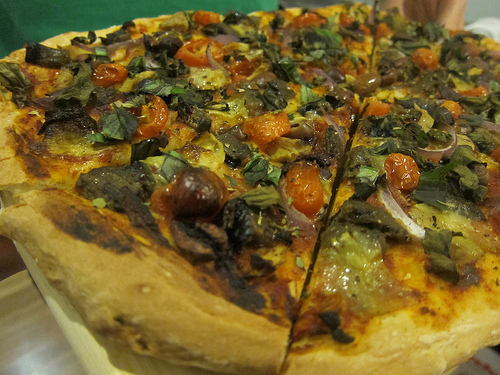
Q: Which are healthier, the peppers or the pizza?
A: The peppers are healthier than the pizza.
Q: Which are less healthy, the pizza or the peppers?
A: The pizza are less healthy than the peppers.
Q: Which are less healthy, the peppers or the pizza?
A: The pizza are less healthy than the peppers.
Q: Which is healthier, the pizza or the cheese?
A: The cheese is healthier than the pizza.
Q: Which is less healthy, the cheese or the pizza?
A: The pizza is less healthy than the cheese.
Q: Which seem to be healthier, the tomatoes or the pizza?
A: The tomatoes are healthier than the pizza.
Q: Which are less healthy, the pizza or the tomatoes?
A: The pizza are less healthy than the tomatoes.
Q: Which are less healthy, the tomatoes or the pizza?
A: The pizza are less healthy than the tomatoes.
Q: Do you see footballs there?
A: No, there are no footballs.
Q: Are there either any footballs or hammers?
A: No, there are no footballs or hammers.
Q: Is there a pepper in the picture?
A: Yes, there are peppers.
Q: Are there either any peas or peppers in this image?
A: Yes, there are peppers.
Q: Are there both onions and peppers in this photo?
A: Yes, there are both peppers and an onion.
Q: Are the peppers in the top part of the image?
A: Yes, the peppers are in the top of the image.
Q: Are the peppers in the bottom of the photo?
A: No, the peppers are in the top of the image.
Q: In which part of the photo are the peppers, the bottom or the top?
A: The peppers are in the top of the image.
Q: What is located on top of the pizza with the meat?
A: The peppers are on top of the pizza.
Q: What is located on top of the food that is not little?
A: The peppers are on top of the pizza.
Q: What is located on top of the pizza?
A: The peppers are on top of the pizza.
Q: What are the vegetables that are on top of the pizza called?
A: The vegetables are peppers.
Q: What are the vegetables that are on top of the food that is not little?
A: The vegetables are peppers.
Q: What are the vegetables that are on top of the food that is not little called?
A: The vegetables are peppers.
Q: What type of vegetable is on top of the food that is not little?
A: The vegetables are peppers.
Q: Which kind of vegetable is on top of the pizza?
A: The vegetables are peppers.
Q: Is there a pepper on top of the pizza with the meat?
A: Yes, there are peppers on top of the pizza.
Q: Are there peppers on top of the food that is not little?
A: Yes, there are peppers on top of the pizza.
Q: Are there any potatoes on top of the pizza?
A: No, there are peppers on top of the pizza.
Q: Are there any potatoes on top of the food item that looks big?
A: No, there are peppers on top of the pizza.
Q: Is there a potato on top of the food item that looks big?
A: No, there are peppers on top of the pizza.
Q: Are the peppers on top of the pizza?
A: Yes, the peppers are on top of the pizza.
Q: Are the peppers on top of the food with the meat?
A: Yes, the peppers are on top of the pizza.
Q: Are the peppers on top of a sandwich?
A: No, the peppers are on top of the pizza.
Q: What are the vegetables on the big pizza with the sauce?
A: The vegetables are peppers.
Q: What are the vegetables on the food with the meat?
A: The vegetables are peppers.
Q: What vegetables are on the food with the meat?
A: The vegetables are peppers.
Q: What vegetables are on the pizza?
A: The vegetables are peppers.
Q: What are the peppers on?
A: The peppers are on the pizza.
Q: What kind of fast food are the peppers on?
A: The peppers are on the pizza.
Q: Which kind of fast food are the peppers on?
A: The peppers are on the pizza.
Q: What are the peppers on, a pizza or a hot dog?
A: The peppers are on a pizza.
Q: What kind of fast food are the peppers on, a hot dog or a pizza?
A: The peppers are on a pizza.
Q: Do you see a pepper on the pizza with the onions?
A: Yes, there are peppers on the pizza.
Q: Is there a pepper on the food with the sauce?
A: Yes, there are peppers on the pizza.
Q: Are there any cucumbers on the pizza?
A: No, there are peppers on the pizza.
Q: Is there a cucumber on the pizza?
A: No, there are peppers on the pizza.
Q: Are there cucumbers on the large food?
A: No, there are peppers on the pizza.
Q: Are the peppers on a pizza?
A: Yes, the peppers are on a pizza.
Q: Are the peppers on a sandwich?
A: No, the peppers are on a pizza.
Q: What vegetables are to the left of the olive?
A: The vegetables are peppers.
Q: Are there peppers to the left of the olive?
A: Yes, there are peppers to the left of the olive.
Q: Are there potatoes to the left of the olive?
A: No, there are peppers to the left of the olive.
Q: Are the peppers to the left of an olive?
A: Yes, the peppers are to the left of an olive.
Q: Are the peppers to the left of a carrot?
A: No, the peppers are to the left of an olive.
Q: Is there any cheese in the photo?
A: Yes, there is cheese.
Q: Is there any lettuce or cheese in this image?
A: Yes, there is cheese.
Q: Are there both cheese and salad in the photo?
A: No, there is cheese but no salad.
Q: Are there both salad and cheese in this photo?
A: No, there is cheese but no salad.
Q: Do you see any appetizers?
A: No, there are no appetizers.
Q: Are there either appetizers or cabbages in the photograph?
A: No, there are no appetizers or cabbages.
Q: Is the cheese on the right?
A: Yes, the cheese is on the right of the image.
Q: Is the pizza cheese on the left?
A: No, the cheese is on the right of the image.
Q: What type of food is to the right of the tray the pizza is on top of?
A: The food is cheese.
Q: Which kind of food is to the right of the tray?
A: The food is cheese.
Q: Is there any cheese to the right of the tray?
A: Yes, there is cheese to the right of the tray.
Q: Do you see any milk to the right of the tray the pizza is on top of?
A: No, there is cheese to the right of the tray.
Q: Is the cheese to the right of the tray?
A: Yes, the cheese is to the right of the tray.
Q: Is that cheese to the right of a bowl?
A: No, the cheese is to the right of the tray.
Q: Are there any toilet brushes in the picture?
A: No, there are no toilet brushes.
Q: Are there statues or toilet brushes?
A: No, there are no toilet brushes or statues.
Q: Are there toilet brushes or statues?
A: No, there are no toilet brushes or statues.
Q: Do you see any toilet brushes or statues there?
A: No, there are no toilet brushes or statues.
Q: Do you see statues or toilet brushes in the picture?
A: No, there are no toilet brushes or statues.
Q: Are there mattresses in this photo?
A: No, there are no mattresses.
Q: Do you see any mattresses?
A: No, there are no mattresses.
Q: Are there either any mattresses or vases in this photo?
A: No, there are no mattresses or vases.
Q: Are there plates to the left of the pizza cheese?
A: No, there is a tray to the left of the cheese.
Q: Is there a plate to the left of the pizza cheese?
A: No, there is a tray to the left of the cheese.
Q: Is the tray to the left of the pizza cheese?
A: Yes, the tray is to the left of the cheese.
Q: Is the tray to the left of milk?
A: No, the tray is to the left of the cheese.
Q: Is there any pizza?
A: Yes, there is a pizza.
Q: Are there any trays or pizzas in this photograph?
A: Yes, there is a pizza.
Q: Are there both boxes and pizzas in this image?
A: No, there is a pizza but no boxes.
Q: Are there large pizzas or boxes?
A: Yes, there is a large pizza.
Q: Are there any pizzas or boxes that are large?
A: Yes, the pizza is large.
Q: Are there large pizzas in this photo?
A: Yes, there is a large pizza.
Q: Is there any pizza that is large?
A: Yes, there is a pizza that is large.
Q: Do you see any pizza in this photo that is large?
A: Yes, there is a pizza that is large.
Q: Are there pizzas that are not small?
A: Yes, there is a large pizza.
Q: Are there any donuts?
A: No, there are no donuts.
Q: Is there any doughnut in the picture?
A: No, there are no donuts.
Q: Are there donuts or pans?
A: No, there are no donuts or pans.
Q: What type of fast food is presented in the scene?
A: The fast food is a pizza.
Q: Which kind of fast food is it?
A: The food is a pizza.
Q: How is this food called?
A: This is a pizza.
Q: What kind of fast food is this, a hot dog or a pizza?
A: This is a pizza.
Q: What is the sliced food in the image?
A: The food is a pizza.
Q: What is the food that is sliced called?
A: The food is a pizza.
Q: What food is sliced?
A: The food is a pizza.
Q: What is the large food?
A: The food is a pizza.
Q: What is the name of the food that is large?
A: The food is a pizza.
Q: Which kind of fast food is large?
A: The fast food is a pizza.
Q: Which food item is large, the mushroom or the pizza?
A: The pizza is large.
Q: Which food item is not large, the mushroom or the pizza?
A: The mushroom is not large.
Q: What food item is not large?
A: The food item is a mushroom.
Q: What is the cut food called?
A: The food is a pizza.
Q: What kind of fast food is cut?
A: The fast food is a pizza.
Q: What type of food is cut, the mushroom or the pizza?
A: The pizza is cut.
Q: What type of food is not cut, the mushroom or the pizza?
A: The mushroom is not cut.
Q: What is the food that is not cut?
A: The food is a mushroom.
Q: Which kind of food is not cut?
A: The food is a mushroom.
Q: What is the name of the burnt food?
A: The food is a pizza.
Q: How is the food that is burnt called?
A: The food is a pizza.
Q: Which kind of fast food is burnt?
A: The fast food is a pizza.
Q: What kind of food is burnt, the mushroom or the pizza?
A: The pizza is burnt.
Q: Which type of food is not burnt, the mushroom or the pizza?
A: The mushroom is not burnt.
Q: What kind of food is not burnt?
A: The food is a mushroom.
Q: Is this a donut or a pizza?
A: This is a pizza.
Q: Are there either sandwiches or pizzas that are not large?
A: No, there is a pizza but it is large.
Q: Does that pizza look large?
A: Yes, the pizza is large.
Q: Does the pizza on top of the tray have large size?
A: Yes, the pizza is large.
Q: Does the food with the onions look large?
A: Yes, the pizza is large.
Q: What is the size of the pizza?
A: The pizza is large.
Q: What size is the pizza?
A: The pizza is large.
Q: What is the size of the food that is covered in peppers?
A: The pizza is large.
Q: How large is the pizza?
A: The pizza is large.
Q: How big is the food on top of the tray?
A: The pizza is large.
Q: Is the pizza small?
A: No, the pizza is large.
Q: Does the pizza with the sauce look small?
A: No, the pizza is large.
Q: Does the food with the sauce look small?
A: No, the pizza is large.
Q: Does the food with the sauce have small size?
A: No, the pizza is large.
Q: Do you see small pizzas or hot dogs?
A: No, there is a pizza but it is large.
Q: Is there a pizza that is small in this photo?
A: No, there is a pizza but it is large.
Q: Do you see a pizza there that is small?
A: No, there is a pizza but it is large.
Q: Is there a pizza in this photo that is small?
A: No, there is a pizza but it is large.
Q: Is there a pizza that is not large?
A: No, there is a pizza but it is large.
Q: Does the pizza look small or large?
A: The pizza is large.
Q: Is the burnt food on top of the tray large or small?
A: The pizza is large.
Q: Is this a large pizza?
A: Yes, this is a large pizza.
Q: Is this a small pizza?
A: No, this is a large pizza.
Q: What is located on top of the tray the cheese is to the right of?
A: The pizza is on top of the tray.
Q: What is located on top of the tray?
A: The pizza is on top of the tray.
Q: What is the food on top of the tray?
A: The food is a pizza.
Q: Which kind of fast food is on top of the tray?
A: The food is a pizza.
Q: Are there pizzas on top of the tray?
A: Yes, there is a pizza on top of the tray.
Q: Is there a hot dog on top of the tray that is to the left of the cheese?
A: No, there is a pizza on top of the tray.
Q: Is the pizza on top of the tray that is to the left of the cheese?
A: Yes, the pizza is on top of the tray.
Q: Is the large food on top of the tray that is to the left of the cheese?
A: Yes, the pizza is on top of the tray.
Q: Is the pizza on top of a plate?
A: No, the pizza is on top of the tray.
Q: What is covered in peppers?
A: The pizza is covered in peppers.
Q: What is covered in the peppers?
A: The pizza is covered in peppers.